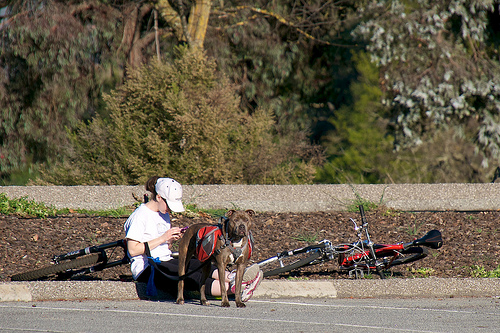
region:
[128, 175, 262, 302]
Woman sitting on the ground playing with phone.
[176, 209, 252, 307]
Brown dog and white dog with backpack.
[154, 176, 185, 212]
The woman is wearing a white hat.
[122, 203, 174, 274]
The woman is wearing a white shirt.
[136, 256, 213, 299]
The woman is wearing black yoga pants.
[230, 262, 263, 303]
The woman is wearing pink and white tennis shoes.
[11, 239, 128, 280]
Black bike to the left of the woman.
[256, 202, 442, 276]
Red bike to the right of the woman.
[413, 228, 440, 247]
Red bike has a black seat.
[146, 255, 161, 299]
Blue ribbon tied to dog leash.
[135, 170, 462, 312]
woman and a dog near a bike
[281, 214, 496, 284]
bike lying on the ground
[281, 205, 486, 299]
red bike on the ground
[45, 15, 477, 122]
green foliage and trees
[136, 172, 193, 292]
woman in a white hat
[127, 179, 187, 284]
woman in a white shirt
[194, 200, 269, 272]
brown dog in a red vest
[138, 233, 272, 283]
woman holding a black leash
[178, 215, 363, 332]
dog standing in parking lot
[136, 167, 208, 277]
woman staring at a phone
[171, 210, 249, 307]
A brown dog standing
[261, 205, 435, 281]
A bike laying down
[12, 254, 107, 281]
Front wheel of a bike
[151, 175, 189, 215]
White hat on a woman's head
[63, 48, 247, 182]
Green bush in the background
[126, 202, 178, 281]
A white shirt on a woman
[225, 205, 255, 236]
The head of a brown dog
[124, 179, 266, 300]
A woman sitting on a curb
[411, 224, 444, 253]
Black seat on a bike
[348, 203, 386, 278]
Handle of a red bike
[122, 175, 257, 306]
a girl with a dog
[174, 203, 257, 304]
a dog with a red vest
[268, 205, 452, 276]
a red bike on the ground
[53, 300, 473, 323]
a concrete parking lot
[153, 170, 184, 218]
a white hat on a girls head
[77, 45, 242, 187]
a cedar tree behind wall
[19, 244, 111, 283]
a black bike wheel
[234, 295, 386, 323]
white lines on a parking lot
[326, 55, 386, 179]
a leafy green tree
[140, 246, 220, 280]
a black lease on the dog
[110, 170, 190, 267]
woman has white cap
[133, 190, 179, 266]
woman has white shirt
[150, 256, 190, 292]
woman has black pants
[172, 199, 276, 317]
woman near brown dog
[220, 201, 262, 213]
dog has brown ears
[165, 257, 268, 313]
dog has brown legs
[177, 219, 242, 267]
red and grey case on dog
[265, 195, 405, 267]
red frame on bike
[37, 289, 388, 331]
white stripes on parking lot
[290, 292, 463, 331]
parking lot is grey